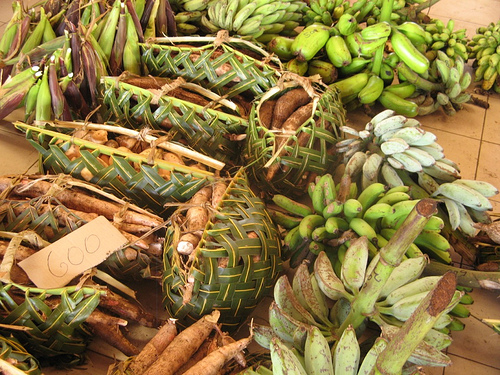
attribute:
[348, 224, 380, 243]
banana — ripe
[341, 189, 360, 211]
banana — ripe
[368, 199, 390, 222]
banana — ripe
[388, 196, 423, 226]
banana — ripe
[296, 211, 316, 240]
banana — ripe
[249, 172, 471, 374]
fruits — bunched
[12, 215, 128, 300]
sign — cardboard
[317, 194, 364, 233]
bananas — green